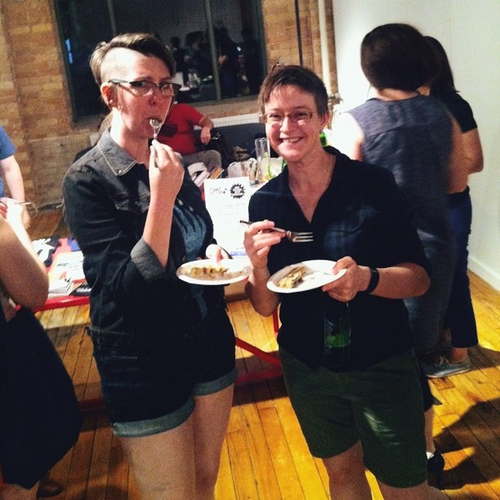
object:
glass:
[253, 135, 273, 179]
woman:
[63, 33, 236, 499]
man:
[158, 103, 222, 174]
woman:
[421, 33, 485, 379]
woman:
[328, 22, 468, 489]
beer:
[320, 289, 351, 375]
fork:
[147, 117, 162, 146]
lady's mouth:
[145, 113, 166, 126]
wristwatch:
[359, 265, 381, 297]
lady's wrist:
[362, 265, 376, 295]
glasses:
[111, 84, 176, 97]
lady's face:
[126, 55, 174, 134]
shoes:
[429, 358, 478, 379]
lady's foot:
[423, 349, 471, 378]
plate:
[172, 256, 253, 286]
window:
[42, 1, 267, 132]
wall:
[0, 2, 339, 204]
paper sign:
[201, 175, 248, 253]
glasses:
[260, 105, 326, 125]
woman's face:
[259, 83, 322, 159]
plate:
[262, 257, 350, 292]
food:
[185, 263, 239, 280]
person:
[0, 194, 82, 499]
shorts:
[87, 323, 239, 439]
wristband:
[363, 265, 380, 296]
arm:
[359, 264, 431, 299]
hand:
[241, 220, 289, 270]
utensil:
[148, 109, 166, 149]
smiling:
[273, 133, 306, 142]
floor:
[0, 271, 499, 499]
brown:
[0, 265, 499, 500]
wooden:
[1, 261, 497, 500]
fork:
[237, 219, 314, 242]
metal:
[237, 216, 316, 244]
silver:
[238, 218, 312, 245]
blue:
[431, 365, 454, 375]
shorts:
[280, 345, 429, 489]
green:
[310, 390, 340, 441]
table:
[16, 219, 295, 386]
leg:
[224, 323, 286, 369]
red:
[238, 337, 252, 347]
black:
[368, 264, 378, 288]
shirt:
[62, 127, 246, 367]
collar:
[94, 128, 134, 178]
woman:
[240, 64, 435, 499]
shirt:
[337, 95, 453, 231]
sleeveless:
[331, 108, 365, 162]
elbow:
[9, 270, 63, 315]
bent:
[26, 262, 56, 313]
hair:
[360, 22, 432, 90]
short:
[357, 24, 432, 104]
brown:
[359, 22, 427, 93]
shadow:
[428, 394, 498, 489]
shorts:
[87, 318, 241, 442]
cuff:
[106, 394, 198, 443]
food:
[272, 260, 308, 289]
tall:
[251, 129, 272, 182]